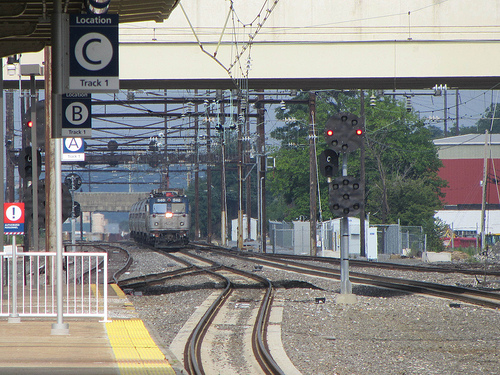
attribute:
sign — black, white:
[67, 9, 120, 92]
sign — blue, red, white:
[4, 199, 27, 239]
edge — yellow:
[91, 280, 169, 370]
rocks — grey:
[10, 240, 484, 368]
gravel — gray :
[132, 250, 497, 373]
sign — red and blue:
[4, 193, 22, 232]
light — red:
[23, 115, 34, 130]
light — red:
[355, 128, 365, 136]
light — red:
[321, 127, 342, 137]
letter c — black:
[78, 37, 109, 68]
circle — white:
[68, 102, 88, 126]